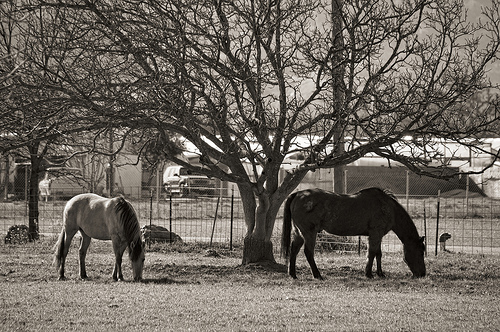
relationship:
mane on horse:
[117, 197, 144, 251] [51, 193, 147, 281]